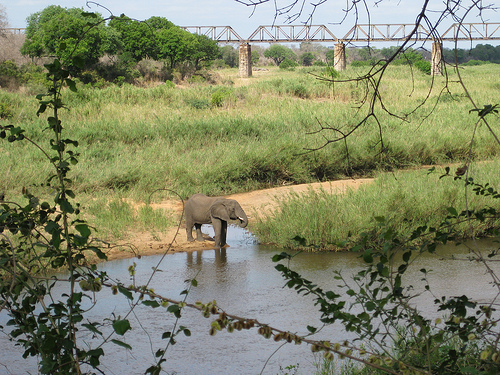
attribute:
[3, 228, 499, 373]
water — very calm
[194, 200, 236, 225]
fur — grey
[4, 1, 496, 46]
sky — clear , blue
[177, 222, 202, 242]
leg — hind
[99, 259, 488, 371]
water — dark brown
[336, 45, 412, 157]
tree branches — bare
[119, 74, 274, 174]
grass — tall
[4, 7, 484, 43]
sky — blue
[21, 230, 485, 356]
stream — medium sized, water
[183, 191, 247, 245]
elephant — baby